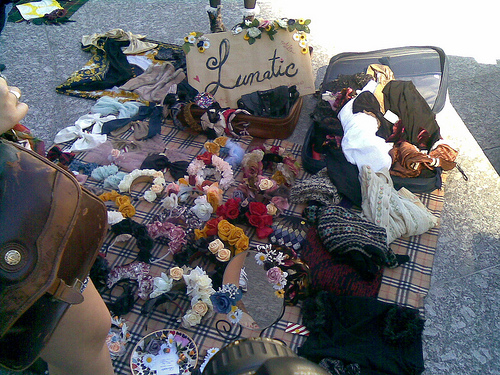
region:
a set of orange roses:
[213, 219, 248, 253]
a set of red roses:
[241, 199, 270, 236]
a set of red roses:
[213, 199, 240, 220]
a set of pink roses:
[208, 153, 235, 178]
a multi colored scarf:
[307, 202, 404, 269]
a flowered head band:
[118, 163, 164, 203]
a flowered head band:
[143, 268, 214, 328]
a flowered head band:
[102, 217, 150, 268]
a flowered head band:
[143, 220, 183, 262]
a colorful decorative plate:
[130, 326, 199, 371]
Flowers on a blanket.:
[143, 160, 240, 314]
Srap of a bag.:
[46, 274, 88, 310]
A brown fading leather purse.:
[1, 130, 123, 372]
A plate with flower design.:
[129, 316, 203, 373]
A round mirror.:
[209, 247, 299, 338]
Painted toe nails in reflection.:
[230, 298, 263, 330]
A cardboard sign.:
[177, 25, 317, 108]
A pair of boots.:
[203, 1, 269, 40]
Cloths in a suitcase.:
[315, 37, 457, 202]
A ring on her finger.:
[2, 87, 30, 109]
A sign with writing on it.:
[174, 20, 326, 113]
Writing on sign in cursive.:
[171, 19, 325, 111]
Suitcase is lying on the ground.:
[303, 2, 495, 194]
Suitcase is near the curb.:
[304, 6, 499, 211]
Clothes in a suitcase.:
[296, 5, 499, 214]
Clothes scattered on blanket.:
[12, 17, 467, 372]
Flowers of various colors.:
[43, 17, 476, 373]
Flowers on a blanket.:
[12, 5, 489, 372]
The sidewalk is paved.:
[2, 2, 499, 370]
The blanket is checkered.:
[3, 93, 462, 370]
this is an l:
[198, 42, 232, 102]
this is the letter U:
[232, 70, 249, 90]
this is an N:
[247, 71, 261, 92]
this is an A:
[258, 66, 275, 83]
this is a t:
[269, 46, 282, 81]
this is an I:
[276, 55, 288, 77]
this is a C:
[285, 56, 299, 78]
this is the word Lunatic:
[200, 42, 304, 102]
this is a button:
[0, 237, 30, 271]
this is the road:
[459, 289, 484, 329]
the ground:
[336, 130, 492, 355]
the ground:
[341, 181, 421, 355]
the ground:
[411, 161, 477, 349]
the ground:
[459, 151, 491, 237]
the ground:
[400, 218, 464, 358]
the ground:
[460, 253, 482, 293]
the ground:
[454, 232, 489, 302]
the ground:
[441, 221, 487, 326]